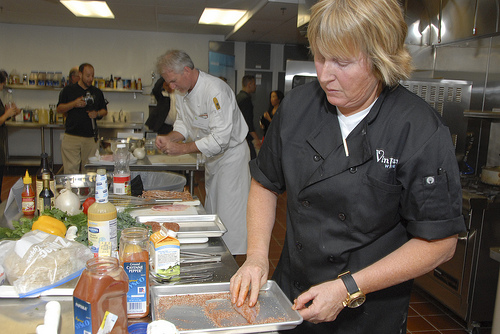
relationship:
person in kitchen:
[228, 2, 471, 328] [5, 1, 498, 330]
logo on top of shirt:
[377, 146, 399, 173] [231, 106, 473, 329]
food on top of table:
[147, 221, 183, 232] [3, 187, 251, 333]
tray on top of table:
[146, 277, 307, 333] [3, 187, 251, 333]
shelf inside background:
[8, 77, 141, 91] [3, 22, 240, 181]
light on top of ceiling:
[60, 1, 115, 22] [3, 3, 309, 44]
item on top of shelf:
[28, 70, 39, 84] [0, 77, 145, 93]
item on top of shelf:
[28, 70, 39, 84] [8, 77, 141, 91]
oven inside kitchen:
[420, 176, 489, 324] [5, 1, 498, 330]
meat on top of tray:
[230, 293, 271, 325] [146, 277, 307, 333]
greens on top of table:
[14, 212, 142, 248] [3, 187, 251, 333]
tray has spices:
[146, 277, 307, 333] [157, 294, 231, 324]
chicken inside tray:
[230, 293, 271, 325] [146, 277, 307, 333]